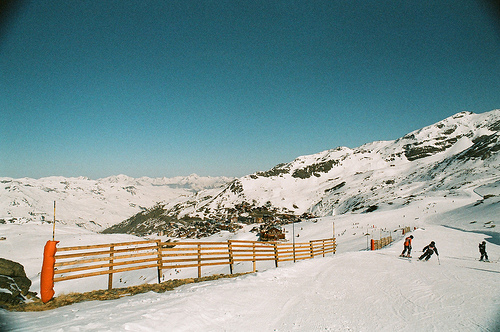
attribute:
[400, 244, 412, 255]
pant — black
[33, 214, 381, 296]
slats — wooden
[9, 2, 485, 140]
sky — clear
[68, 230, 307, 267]
railing — orange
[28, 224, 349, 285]
fence — orange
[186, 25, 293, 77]
sky — cloudless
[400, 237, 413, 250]
jacket — red